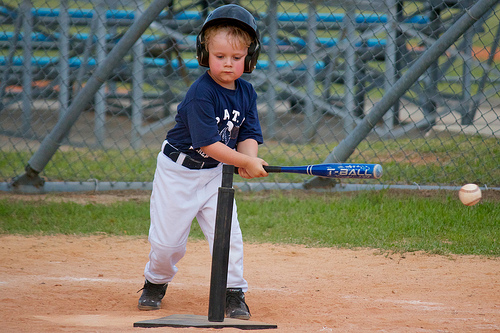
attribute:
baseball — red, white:
[457, 183, 483, 207]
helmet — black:
[196, 3, 260, 75]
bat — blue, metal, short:
[235, 160, 386, 183]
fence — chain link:
[1, 2, 499, 195]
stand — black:
[132, 165, 274, 331]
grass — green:
[2, 135, 500, 261]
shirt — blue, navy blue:
[166, 71, 264, 167]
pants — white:
[147, 139, 250, 292]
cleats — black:
[137, 275, 249, 320]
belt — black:
[162, 140, 226, 171]